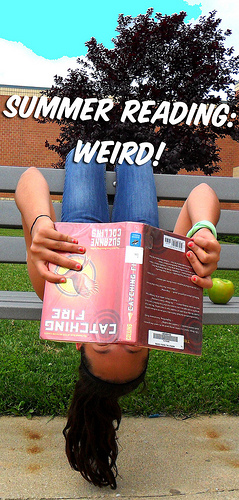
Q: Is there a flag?
A: No, there are no flags.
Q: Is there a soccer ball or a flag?
A: No, there are no flags or soccer balls.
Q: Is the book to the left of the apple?
A: Yes, the book is to the left of the apple.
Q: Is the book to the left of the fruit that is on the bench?
A: Yes, the book is to the left of the apple.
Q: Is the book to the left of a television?
A: No, the book is to the left of the apple.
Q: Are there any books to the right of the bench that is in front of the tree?
A: Yes, there is a book to the right of the bench.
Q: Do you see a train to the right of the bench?
A: No, there is a book to the right of the bench.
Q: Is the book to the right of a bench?
A: Yes, the book is to the right of a bench.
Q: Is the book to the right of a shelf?
A: No, the book is to the right of a bench.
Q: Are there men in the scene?
A: No, there are no men.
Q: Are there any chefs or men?
A: No, there are no men or chefs.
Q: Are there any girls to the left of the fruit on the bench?
A: Yes, there is a girl to the left of the apple.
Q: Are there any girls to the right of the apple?
A: No, the girl is to the left of the apple.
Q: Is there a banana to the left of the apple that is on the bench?
A: No, there is a girl to the left of the apple.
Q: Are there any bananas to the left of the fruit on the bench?
A: No, there is a girl to the left of the apple.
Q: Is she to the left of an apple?
A: Yes, the girl is to the left of an apple.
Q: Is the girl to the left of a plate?
A: No, the girl is to the left of an apple.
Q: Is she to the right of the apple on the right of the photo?
A: No, the girl is to the left of the apple.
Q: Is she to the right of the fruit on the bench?
A: No, the girl is to the left of the apple.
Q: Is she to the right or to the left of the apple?
A: The girl is to the left of the apple.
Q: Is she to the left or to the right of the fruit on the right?
A: The girl is to the left of the apple.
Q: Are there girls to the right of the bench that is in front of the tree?
A: Yes, there is a girl to the right of the bench.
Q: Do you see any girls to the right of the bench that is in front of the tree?
A: Yes, there is a girl to the right of the bench.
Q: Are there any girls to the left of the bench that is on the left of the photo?
A: No, the girl is to the right of the bench.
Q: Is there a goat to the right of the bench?
A: No, there is a girl to the right of the bench.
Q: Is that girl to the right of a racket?
A: No, the girl is to the right of the bench.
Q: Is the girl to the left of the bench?
A: No, the girl is to the right of the bench.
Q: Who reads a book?
A: The girl reads a book.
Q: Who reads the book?
A: The girl reads a book.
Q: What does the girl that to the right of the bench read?
A: The girl reads a book.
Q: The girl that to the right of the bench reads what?
A: The girl reads a book.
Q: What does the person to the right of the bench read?
A: The girl reads a book.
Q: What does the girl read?
A: The girl reads a book.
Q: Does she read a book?
A: Yes, the girl reads a book.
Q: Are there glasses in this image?
A: No, there are no glasses.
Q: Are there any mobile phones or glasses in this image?
A: No, there are no glasses or mobile phones.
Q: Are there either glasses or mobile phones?
A: No, there are no glasses or mobile phones.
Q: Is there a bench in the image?
A: Yes, there is a bench.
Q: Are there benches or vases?
A: Yes, there is a bench.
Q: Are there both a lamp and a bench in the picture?
A: No, there is a bench but no lamps.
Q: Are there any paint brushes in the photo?
A: No, there are no paint brushes.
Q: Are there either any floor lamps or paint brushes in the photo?
A: No, there are no paint brushes or floor lamps.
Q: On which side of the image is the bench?
A: The bench is on the left of the image.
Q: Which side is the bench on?
A: The bench is on the left of the image.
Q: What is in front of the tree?
A: The bench is in front of the tree.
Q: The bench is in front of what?
A: The bench is in front of the tree.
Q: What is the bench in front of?
A: The bench is in front of the tree.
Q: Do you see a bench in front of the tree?
A: Yes, there is a bench in front of the tree.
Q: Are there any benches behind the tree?
A: No, the bench is in front of the tree.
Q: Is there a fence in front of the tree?
A: No, there is a bench in front of the tree.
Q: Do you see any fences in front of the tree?
A: No, there is a bench in front of the tree.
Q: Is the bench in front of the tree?
A: Yes, the bench is in front of the tree.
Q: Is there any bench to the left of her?
A: Yes, there is a bench to the left of the girl.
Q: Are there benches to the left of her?
A: Yes, there is a bench to the left of the girl.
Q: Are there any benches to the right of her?
A: No, the bench is to the left of the girl.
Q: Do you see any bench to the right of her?
A: No, the bench is to the left of the girl.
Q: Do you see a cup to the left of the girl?
A: No, there is a bench to the left of the girl.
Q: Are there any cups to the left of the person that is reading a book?
A: No, there is a bench to the left of the girl.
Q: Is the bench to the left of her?
A: Yes, the bench is to the left of the girl.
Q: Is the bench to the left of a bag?
A: No, the bench is to the left of the girl.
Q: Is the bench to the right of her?
A: No, the bench is to the left of a girl.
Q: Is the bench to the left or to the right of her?
A: The bench is to the left of the girl.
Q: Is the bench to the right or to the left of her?
A: The bench is to the left of the girl.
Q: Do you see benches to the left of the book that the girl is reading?
A: Yes, there is a bench to the left of the book.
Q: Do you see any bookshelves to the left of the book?
A: No, there is a bench to the left of the book.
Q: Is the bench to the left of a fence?
A: No, the bench is to the left of the book.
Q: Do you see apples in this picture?
A: Yes, there is an apple.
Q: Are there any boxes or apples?
A: Yes, there is an apple.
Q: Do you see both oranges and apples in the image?
A: No, there is an apple but no oranges.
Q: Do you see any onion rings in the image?
A: No, there are no onion rings.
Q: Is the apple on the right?
A: Yes, the apple is on the right of the image.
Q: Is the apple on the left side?
A: No, the apple is on the right of the image.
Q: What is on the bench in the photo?
A: The apple is on the bench.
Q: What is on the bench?
A: The apple is on the bench.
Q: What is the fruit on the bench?
A: The fruit is an apple.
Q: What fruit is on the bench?
A: The fruit is an apple.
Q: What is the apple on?
A: The apple is on the bench.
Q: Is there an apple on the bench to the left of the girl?
A: Yes, there is an apple on the bench.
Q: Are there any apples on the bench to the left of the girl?
A: Yes, there is an apple on the bench.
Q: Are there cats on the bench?
A: No, there is an apple on the bench.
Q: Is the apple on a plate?
A: No, the apple is on the bench.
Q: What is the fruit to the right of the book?
A: The fruit is an apple.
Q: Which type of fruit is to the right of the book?
A: The fruit is an apple.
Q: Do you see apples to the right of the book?
A: Yes, there is an apple to the right of the book.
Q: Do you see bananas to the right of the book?
A: No, there is an apple to the right of the book.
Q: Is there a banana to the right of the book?
A: No, there is an apple to the right of the book.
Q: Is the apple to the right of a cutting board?
A: No, the apple is to the right of the book.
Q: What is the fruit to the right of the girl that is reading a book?
A: The fruit is an apple.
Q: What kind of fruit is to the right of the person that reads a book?
A: The fruit is an apple.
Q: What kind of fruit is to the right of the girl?
A: The fruit is an apple.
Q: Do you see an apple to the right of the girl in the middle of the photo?
A: Yes, there is an apple to the right of the girl.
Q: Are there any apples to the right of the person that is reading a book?
A: Yes, there is an apple to the right of the girl.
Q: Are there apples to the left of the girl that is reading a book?
A: No, the apple is to the right of the girl.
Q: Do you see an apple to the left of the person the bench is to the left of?
A: No, the apple is to the right of the girl.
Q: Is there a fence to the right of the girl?
A: No, there is an apple to the right of the girl.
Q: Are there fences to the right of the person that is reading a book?
A: No, there is an apple to the right of the girl.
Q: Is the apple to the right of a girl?
A: Yes, the apple is to the right of a girl.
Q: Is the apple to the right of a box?
A: No, the apple is to the right of a girl.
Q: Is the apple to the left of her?
A: No, the apple is to the right of the girl.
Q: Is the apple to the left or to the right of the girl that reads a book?
A: The apple is to the right of the girl.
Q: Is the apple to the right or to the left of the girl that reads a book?
A: The apple is to the right of the girl.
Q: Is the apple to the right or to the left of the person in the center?
A: The apple is to the right of the girl.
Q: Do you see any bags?
A: No, there are no bags.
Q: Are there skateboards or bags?
A: No, there are no bags or skateboards.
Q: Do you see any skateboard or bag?
A: No, there are no bags or skateboards.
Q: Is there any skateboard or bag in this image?
A: No, there are no bags or skateboards.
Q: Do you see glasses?
A: No, there are no glasses.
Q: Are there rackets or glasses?
A: No, there are no glasses or rackets.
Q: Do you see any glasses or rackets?
A: No, there are no glasses or rackets.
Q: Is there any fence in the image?
A: No, there are no fences.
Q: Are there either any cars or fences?
A: No, there are no fences or cars.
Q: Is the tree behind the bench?
A: Yes, the tree is behind the bench.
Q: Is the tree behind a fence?
A: No, the tree is behind the bench.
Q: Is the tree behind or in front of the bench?
A: The tree is behind the bench.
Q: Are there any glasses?
A: No, there are no glasses.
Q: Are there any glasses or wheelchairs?
A: No, there are no glasses or wheelchairs.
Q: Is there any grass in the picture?
A: Yes, there is grass.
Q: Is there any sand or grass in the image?
A: Yes, there is grass.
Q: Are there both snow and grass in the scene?
A: No, there is grass but no snow.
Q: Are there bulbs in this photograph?
A: No, there are no bulbs.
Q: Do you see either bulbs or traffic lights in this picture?
A: No, there are no bulbs or traffic lights.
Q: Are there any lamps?
A: No, there are no lamps.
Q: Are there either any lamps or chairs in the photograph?
A: No, there are no lamps or chairs.